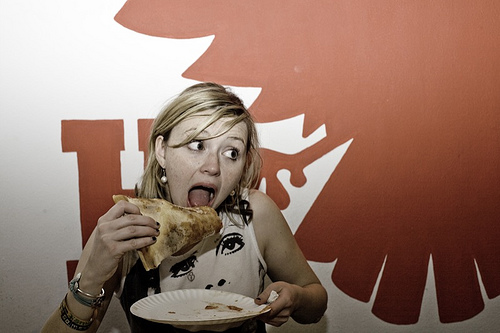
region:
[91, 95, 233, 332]
woman eating slice of pizza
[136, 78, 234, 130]
blonde hair on woman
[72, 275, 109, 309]
bracelets on woman's arm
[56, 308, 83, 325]
bracelets on woman's arm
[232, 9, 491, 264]
red bird symbol on wall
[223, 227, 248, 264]
eye on white shirt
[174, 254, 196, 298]
eye on white shirt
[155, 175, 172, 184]
white earring hanging from ear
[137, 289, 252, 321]
white paper plate under pizza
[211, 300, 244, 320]
tomato sauce on plate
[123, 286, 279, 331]
Woman holding a plate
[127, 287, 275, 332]
Woman is holding a plate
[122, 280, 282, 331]
Woman holding a white plate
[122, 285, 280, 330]
Woman is holding a white plate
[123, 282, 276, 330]
Woman holding a paper plate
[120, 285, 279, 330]
Woman is holding a paper plate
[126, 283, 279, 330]
Woman holding a round plate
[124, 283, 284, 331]
Woman is holding a round plate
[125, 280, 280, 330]
Woman holding a white paper plate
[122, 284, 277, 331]
Woman is holding a white paper plate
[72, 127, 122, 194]
the letter is red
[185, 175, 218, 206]
her mouth is open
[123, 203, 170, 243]
she's holding the pizza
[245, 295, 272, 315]
she's holding the plate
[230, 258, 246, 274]
the shirt is white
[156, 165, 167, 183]
she's wearing earrings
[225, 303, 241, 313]
the sauce is on the plate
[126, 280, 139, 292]
the shirt is black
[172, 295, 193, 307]
the plate is white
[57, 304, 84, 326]
she's wearing bracelets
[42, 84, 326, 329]
a woman eating a slice of pizza and holding a plate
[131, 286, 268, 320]
a white paper plate in woman's hand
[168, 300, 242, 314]
stains on a white paper plate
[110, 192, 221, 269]
a slice of pizza about to enter woman's mouth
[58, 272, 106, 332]
woman wearing colorful bracelets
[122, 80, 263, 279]
woman with long blonde hair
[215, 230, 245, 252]
drawing of a black eye on a white shirt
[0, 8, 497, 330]
a white and red wall behind a woman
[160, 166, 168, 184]
a white pearl earring dangling from woman's ear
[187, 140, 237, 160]
a woman with brown eyes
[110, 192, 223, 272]
a slice of pizza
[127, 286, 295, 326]
a white paper plate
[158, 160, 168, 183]
an earring in the woman's ear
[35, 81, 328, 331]
a woman holding a paper plate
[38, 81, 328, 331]
a woman eating a slice of pizza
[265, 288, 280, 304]
a napkin in the woman's hand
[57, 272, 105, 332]
bracelets on the woman's right wrist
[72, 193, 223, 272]
a slice of pizza in the woman's right hand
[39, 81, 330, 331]
a young lady holding a pizza slice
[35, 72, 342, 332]
a woman standing up while eating pizza